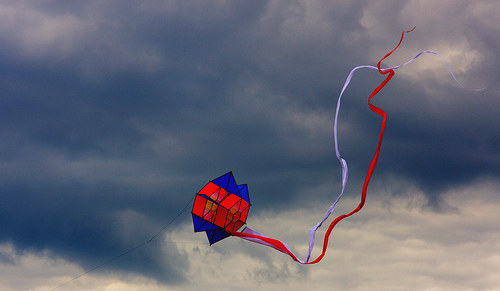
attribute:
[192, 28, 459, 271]
kite — red, blue, flying, diamond shaped, winged, tipped, pyramid shaped, parallel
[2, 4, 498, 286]
sky — blue, stormy, lighter, cloudy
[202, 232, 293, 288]
string — long, red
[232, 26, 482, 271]
tail — long, red, entwined, lavender, crossed